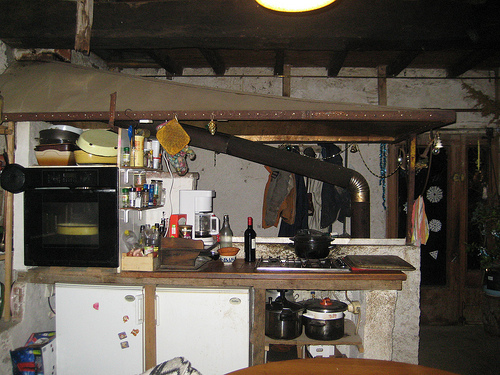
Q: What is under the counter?
A: Pots on a shelf.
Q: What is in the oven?
A: A yellow pan.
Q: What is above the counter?
A: A stove.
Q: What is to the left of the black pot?
A: A black bottle.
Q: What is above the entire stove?
A: A hood/roof.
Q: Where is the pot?
A: On the burner of the stove.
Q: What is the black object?
A: Stove.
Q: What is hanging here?
A: Assorted coats.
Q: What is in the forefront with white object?
A: Fridge.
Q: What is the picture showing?
A: A kitchen.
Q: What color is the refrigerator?
A: White.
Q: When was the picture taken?
A: At night.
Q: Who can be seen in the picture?
A: No one.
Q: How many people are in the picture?
A: None.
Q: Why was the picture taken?
A: To capture the kitchen.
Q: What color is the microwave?
A: Black.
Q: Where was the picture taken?
A: Outside cabana.